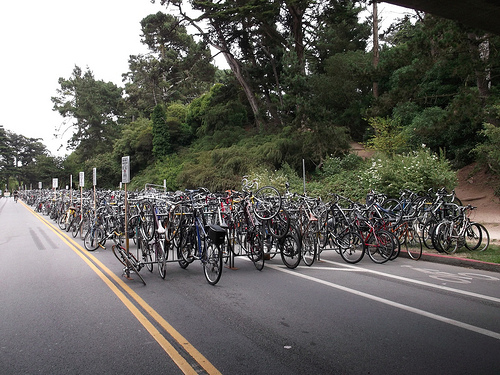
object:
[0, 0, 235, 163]
sky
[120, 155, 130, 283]
sign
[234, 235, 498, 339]
lines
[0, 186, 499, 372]
street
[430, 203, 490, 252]
bikes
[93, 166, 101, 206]
pole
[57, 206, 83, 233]
bicycles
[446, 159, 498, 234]
trail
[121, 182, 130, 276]
post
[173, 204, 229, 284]
bike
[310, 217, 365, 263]
bike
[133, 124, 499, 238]
hill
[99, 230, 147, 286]
bike rack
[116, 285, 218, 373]
lines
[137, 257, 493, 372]
road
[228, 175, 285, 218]
bike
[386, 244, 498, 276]
curb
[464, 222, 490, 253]
tire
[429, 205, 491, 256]
bicycle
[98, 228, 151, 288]
bike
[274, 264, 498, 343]
white lines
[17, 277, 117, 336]
road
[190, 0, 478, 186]
trees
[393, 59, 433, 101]
leaves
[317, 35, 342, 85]
leaves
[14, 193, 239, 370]
lines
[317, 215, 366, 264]
bike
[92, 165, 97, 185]
sign